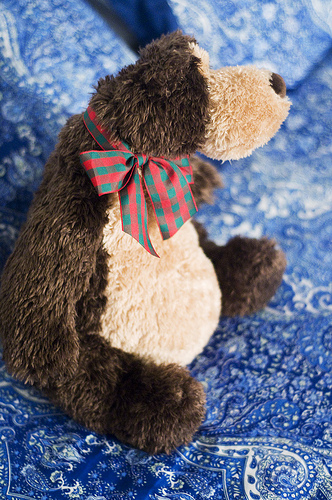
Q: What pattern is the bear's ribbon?
A: Plaid.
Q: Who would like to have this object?
A: A child.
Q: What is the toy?
A: A teddy bear.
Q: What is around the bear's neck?
A: A ribbon.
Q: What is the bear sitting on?
A: A blue cloth.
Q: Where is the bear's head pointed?
A: To the right.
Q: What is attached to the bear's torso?
A: Arms and legs.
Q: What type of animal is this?
A: Bear.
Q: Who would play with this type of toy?
A: A child.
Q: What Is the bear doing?
A: Sitting on the bed.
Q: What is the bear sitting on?
A: The bed.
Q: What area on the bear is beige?
A: The Bears stomach.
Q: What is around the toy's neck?
A: Ribbon.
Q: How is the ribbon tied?
A: Bow.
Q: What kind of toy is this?
A: Stuffed animal.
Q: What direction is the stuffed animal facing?
A: Right.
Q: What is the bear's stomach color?
A: Tan.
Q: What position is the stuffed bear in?
A: Sitting.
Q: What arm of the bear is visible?
A: Right.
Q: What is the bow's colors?
A: Red and green.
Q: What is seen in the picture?
A: Doll.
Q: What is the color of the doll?
A: Brown.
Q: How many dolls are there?
A: 1.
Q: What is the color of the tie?
A: Red and blue.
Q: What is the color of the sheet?
A: Blue.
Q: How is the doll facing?
A: Towards the side.